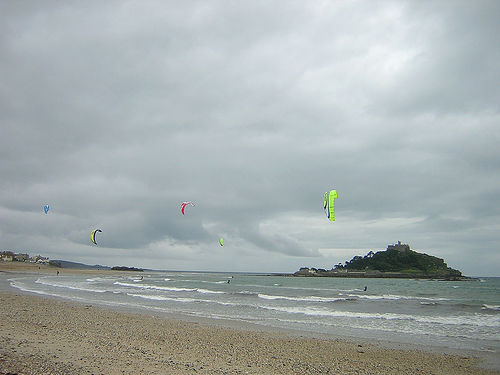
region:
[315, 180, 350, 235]
kite in the sky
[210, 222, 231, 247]
kite in the sky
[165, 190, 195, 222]
kite in the sky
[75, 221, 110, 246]
kite in the sky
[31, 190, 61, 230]
kite in the sky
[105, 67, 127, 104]
kite in the sky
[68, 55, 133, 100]
white clouds in blue sky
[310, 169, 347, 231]
kite in sky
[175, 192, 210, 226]
kite in sky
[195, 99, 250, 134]
white clouds in blue sky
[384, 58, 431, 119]
white clouds in blue sky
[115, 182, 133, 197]
white clouds in blue sky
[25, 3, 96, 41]
white clouds in blue sky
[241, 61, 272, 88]
white clouds in blue sky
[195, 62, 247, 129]
white clouds in blue sky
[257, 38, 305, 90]
white clouds in blue sky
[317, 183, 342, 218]
kite in sky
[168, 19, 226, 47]
white clouds in blue sky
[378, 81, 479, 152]
white clouds in blue sky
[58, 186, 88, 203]
white clouds in blue sky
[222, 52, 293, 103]
white clouds in blue sky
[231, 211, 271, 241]
white clouds in blue sky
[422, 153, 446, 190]
white clouds in blue sky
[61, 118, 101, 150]
white clouds in blue sky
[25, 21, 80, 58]
white clouds in blue sky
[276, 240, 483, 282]
Island in the water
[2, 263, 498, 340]
Waves on the beach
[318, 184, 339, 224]
Neon yellow kite in the sky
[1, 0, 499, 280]
Grey clouds in the sky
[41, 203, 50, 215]
Blue kite in the sky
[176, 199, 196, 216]
Red and white kite in the sky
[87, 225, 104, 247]
Yellow and black kite in the sky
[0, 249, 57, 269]
Buildings near the beach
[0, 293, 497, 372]
Sand on the beach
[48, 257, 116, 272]
Mountains near the beach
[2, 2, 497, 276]
Cloudy blue and grey sky.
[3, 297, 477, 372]
This side of a sandy beach.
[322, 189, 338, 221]
Largest bright green kite.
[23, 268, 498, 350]
Grey body of water.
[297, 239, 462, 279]
Distant piece of brown and green land.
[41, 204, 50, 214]
A blue flying kite.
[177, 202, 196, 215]
A red flying kite.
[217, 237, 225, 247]
Furthest yellow kite.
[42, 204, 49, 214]
A blue kite in the sky.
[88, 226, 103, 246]
Yellow and black kite.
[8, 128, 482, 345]
kites in the sky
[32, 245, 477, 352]
waves in the water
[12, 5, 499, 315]
a grey overcast day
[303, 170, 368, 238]
a lime green kite